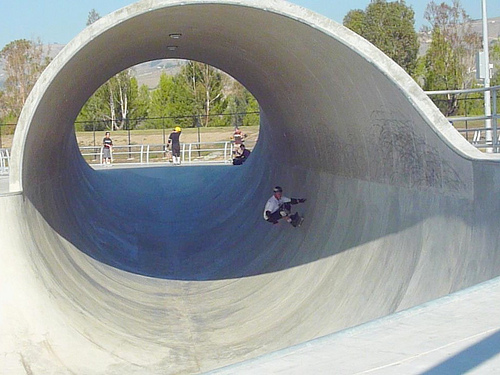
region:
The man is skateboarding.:
[243, 176, 323, 238]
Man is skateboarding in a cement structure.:
[68, 53, 389, 295]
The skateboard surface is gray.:
[76, 168, 242, 341]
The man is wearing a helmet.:
[258, 175, 293, 201]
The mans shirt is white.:
[256, 188, 299, 215]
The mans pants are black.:
[258, 198, 298, 233]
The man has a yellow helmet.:
[168, 124, 184, 136]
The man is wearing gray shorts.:
[98, 143, 120, 157]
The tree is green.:
[146, 69, 195, 131]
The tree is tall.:
[143, 67, 195, 126]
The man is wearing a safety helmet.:
[264, 173, 284, 199]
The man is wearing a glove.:
[287, 189, 312, 211]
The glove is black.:
[289, 196, 314, 205]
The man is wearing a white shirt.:
[255, 190, 298, 216]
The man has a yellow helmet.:
[171, 112, 191, 142]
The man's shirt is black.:
[98, 138, 120, 153]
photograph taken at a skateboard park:
[17, 13, 465, 366]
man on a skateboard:
[247, 170, 334, 243]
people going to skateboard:
[102, 109, 262, 174]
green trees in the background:
[11, 23, 472, 121]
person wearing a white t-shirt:
[252, 183, 319, 234]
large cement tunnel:
[30, 28, 465, 346]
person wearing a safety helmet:
[240, 177, 313, 233]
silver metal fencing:
[437, 81, 498, 146]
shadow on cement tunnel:
[43, 105, 433, 278]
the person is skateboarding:
[183, 141, 370, 277]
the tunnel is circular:
[11, 3, 411, 283]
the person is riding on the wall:
[238, 165, 314, 239]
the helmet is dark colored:
[260, 175, 287, 199]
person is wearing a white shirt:
[247, 170, 305, 224]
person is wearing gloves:
[262, 195, 319, 234]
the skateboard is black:
[282, 208, 309, 235]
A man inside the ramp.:
[221, 170, 322, 230]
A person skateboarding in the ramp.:
[226, 172, 321, 237]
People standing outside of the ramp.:
[95, 115, 268, 166]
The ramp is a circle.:
[48, 20, 397, 273]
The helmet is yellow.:
[170, 120, 196, 135]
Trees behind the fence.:
[61, 22, 456, 103]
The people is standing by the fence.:
[83, 125, 252, 161]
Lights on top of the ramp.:
[170, 27, 189, 62]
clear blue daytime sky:
[1, 0, 498, 55]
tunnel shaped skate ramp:
[5, 1, 496, 373]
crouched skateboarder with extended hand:
[263, 186, 308, 225]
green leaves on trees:
[345, 1, 417, 82]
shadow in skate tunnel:
[23, 2, 455, 281]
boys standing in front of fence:
[102, 126, 250, 165]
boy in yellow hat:
[164, 126, 181, 163]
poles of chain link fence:
[75, 110, 260, 160]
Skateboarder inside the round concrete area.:
[263, 187, 306, 226]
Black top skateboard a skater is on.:
[289, 212, 306, 228]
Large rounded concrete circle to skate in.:
[4, 4, 447, 344]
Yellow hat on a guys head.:
[173, 125, 182, 133]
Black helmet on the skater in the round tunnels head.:
[271, 184, 283, 194]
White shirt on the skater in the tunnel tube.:
[263, 194, 291, 221]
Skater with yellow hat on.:
[163, 126, 185, 166]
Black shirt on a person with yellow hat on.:
[167, 131, 182, 147]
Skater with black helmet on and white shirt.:
[263, 185, 306, 225]